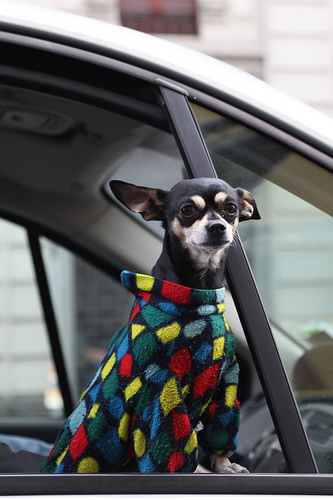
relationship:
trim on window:
[159, 79, 328, 471] [186, 96, 333, 473]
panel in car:
[245, 404, 332, 474] [1, 3, 331, 498]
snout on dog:
[193, 209, 231, 249] [38, 177, 263, 474]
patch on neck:
[188, 244, 226, 268] [162, 231, 227, 289]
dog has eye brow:
[38, 177, 263, 474] [187, 195, 206, 207]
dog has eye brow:
[38, 177, 263, 474] [211, 191, 228, 204]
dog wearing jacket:
[38, 177, 263, 474] [33, 268, 243, 475]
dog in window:
[38, 177, 263, 474] [1, 39, 290, 477]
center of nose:
[202, 210, 223, 221] [192, 210, 233, 250]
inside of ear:
[239, 199, 253, 215] [234, 185, 261, 224]